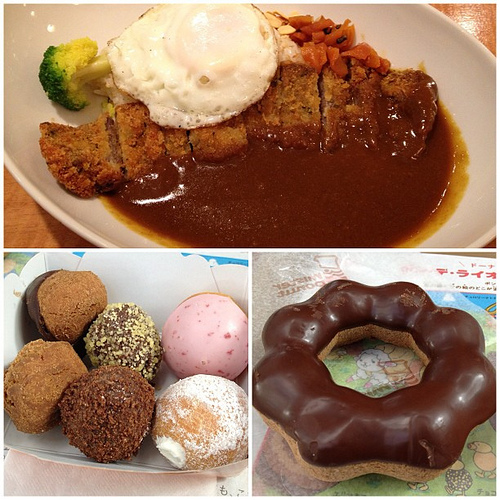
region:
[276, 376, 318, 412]
chocolate frosting on a crueller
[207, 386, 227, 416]
white powdered sugar toppping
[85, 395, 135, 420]
toasted brown coconut topping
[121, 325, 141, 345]
finely chopped almond topping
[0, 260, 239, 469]
a variety of doughnut holes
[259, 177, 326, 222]
brown gravy on plate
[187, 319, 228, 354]
pink strawberry icing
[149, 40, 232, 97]
a dollop of mashed potatoes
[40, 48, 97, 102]
a piece of green broccoli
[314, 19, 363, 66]
chopped carrots on the side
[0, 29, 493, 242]
white plate with food on it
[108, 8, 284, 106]
a fried egg on a plate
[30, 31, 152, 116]
a piece of broccoli on a plate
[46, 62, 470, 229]
a piece of meat with gravy on a plate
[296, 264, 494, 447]
a doughnut with chocolate frosting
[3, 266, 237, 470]
six doughnut holes in a paper bowl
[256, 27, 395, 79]
sliced tomato on a plate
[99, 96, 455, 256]
brown gravy on a plate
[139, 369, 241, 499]
a doughnut hole with powder sugar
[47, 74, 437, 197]
cut meat on a plate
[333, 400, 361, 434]
part of a choco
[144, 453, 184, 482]
edge of a box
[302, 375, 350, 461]
part of a doughnut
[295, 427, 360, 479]
edge of a doughnut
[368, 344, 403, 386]
part of a space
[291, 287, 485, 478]
chocolate on top of the donut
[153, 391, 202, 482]
cream inside the donut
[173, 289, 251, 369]
donut has pink frosting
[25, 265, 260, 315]
donuts sitting in a paper bowl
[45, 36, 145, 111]
brocolli next to egg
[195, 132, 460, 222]
gravy on the plate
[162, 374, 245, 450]
powder sugar on the donut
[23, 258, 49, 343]
donut has chocolate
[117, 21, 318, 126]
fried egg on the plate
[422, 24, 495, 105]
plate is white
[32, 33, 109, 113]
Piece of green and yellow broccoli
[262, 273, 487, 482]
Brown chocolate covered donut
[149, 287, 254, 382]
Donut hole with pink icing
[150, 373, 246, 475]
Donut hole with cream and powdered sugar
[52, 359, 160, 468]
Donut hole with chocolate powder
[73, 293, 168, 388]
Chocolate donut hole with yellow powder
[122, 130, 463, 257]
Brown sauce in dish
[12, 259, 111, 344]
Donut hole with chocolate icing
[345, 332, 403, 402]
White cartoon bunny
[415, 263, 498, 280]
Red writing in an Asian language